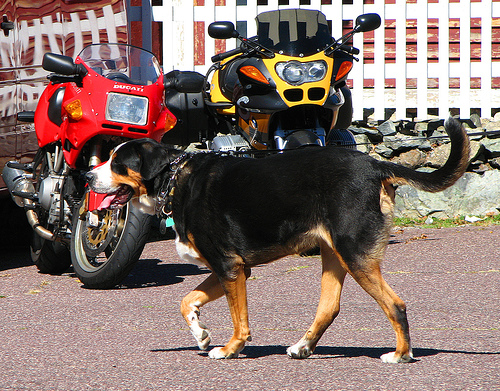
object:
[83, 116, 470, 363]
dog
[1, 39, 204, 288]
surface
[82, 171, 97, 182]
nose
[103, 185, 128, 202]
mouth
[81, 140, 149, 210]
face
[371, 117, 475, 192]
tail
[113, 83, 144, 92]
white letters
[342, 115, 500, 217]
rock wall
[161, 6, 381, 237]
bike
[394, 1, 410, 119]
post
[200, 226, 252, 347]
front legs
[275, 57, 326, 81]
headlight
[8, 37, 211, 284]
bike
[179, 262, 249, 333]
leg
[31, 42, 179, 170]
red front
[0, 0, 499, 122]
fence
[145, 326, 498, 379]
shadow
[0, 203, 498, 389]
ground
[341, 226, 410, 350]
back leg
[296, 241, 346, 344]
back leg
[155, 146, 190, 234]
collar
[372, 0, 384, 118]
post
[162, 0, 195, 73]
post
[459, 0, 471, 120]
post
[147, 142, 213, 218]
bandana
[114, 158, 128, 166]
eye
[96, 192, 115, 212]
tongue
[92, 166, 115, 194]
spot